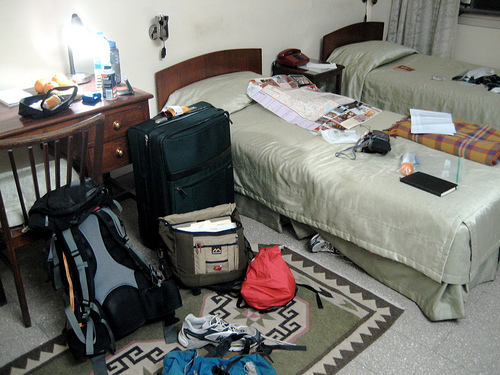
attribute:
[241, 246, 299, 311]
bag — red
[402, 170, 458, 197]
book — black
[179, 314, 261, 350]
sneaker — alone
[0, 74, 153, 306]
desk — small, wooden, brown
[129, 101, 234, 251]
luggage — black, dark green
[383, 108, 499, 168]
blanket — tan, gold, folded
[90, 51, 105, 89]
bottle — empty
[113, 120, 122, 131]
knob — gold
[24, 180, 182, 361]
hiking pack — gray, black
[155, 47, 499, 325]
bed — a twin, made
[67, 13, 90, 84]
lamp — gray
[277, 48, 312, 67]
phone — red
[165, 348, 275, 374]
backpack — blue, black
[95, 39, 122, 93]
bottles — for water